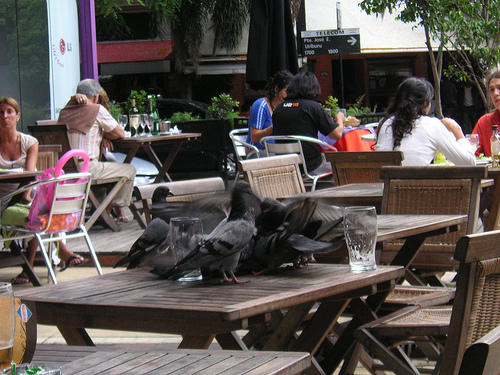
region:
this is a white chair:
[1, 160, 128, 303]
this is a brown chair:
[363, 163, 493, 299]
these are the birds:
[123, 151, 338, 297]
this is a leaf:
[214, 91, 226, 101]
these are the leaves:
[211, 90, 243, 117]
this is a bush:
[161, 76, 256, 157]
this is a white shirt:
[366, 103, 494, 191]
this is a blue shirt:
[241, 96, 301, 171]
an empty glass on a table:
[165, 211, 210, 291]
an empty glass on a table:
[336, 202, 388, 280]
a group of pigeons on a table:
[127, 176, 358, 278]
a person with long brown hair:
[371, 74, 433, 146]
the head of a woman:
[1, 89, 28, 139]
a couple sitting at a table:
[223, 62, 350, 162]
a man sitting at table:
[36, 69, 134, 231]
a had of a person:
[70, 91, 92, 111]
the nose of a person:
[1, 109, 13, 119]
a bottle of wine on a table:
[120, 91, 142, 135]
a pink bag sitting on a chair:
[36, 163, 96, 233]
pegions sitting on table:
[143, 179, 350, 322]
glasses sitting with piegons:
[163, 209, 428, 269]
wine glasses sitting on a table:
[121, 112, 171, 138]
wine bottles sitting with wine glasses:
[124, 98, 165, 125]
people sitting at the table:
[386, 87, 498, 161]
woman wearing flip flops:
[4, 248, 111, 278]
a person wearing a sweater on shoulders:
[61, 95, 117, 144]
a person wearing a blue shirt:
[251, 95, 277, 147]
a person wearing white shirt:
[389, 108, 429, 174]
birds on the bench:
[166, 193, 294, 291]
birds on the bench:
[130, 189, 312, 279]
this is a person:
[44, 62, 149, 224]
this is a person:
[1, 100, 53, 184]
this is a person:
[220, 61, 292, 144]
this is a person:
[266, 75, 365, 164]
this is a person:
[372, 59, 482, 179]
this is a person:
[464, 62, 494, 172]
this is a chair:
[9, 152, 108, 264]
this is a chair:
[235, 142, 337, 238]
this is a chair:
[409, 227, 493, 364]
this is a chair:
[389, 150, 497, 245]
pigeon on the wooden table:
[250, 220, 336, 283]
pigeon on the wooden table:
[191, 197, 262, 284]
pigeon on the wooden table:
[121, 182, 182, 278]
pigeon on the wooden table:
[261, 196, 353, 265]